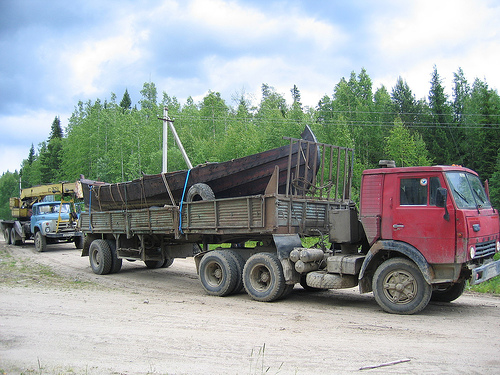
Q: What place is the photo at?
A: It is at the road.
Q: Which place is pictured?
A: It is a road.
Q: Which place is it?
A: It is a road.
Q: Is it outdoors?
A: Yes, it is outdoors.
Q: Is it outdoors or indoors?
A: It is outdoors.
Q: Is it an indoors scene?
A: No, it is outdoors.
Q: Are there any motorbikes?
A: No, there are no motorbikes.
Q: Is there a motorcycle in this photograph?
A: No, there are no motorcycles.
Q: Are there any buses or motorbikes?
A: No, there are no motorbikes or buses.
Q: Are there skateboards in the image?
A: No, there are no skateboards.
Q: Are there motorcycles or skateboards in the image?
A: No, there are no skateboards or motorcycles.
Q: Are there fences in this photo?
A: No, there are no fences.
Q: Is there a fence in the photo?
A: No, there are no fences.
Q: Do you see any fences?
A: No, there are no fences.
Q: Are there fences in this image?
A: No, there are no fences.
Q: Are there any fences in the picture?
A: No, there are no fences.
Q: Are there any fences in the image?
A: No, there are no fences.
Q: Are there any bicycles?
A: No, there are no bicycles.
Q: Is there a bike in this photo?
A: No, there are no bikes.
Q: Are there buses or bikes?
A: No, there are no bikes or buses.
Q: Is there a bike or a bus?
A: No, there are no bikes or buses.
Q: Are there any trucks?
A: Yes, there is a truck.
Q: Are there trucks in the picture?
A: Yes, there is a truck.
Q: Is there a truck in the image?
A: Yes, there is a truck.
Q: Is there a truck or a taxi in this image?
A: Yes, there is a truck.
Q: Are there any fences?
A: No, there are no fences.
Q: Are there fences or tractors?
A: No, there are no fences or tractors.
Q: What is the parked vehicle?
A: The vehicle is a truck.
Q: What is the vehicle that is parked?
A: The vehicle is a truck.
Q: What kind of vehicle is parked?
A: The vehicle is a truck.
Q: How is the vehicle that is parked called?
A: The vehicle is a truck.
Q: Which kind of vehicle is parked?
A: The vehicle is a truck.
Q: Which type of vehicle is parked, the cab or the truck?
A: The truck is parked.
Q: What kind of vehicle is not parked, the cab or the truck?
A: The cab is not parked.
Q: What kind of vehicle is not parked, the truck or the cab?
A: The cab is not parked.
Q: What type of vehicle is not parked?
A: The vehicle is a taxi.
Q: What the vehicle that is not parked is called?
A: The vehicle is a taxi.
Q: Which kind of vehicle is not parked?
A: The vehicle is a taxi.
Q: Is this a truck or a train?
A: This is a truck.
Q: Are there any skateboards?
A: No, there are no skateboards.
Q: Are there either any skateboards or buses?
A: No, there are no skateboards or buses.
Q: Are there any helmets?
A: No, there are no helmets.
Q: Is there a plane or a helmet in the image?
A: No, there are no helmets or airplanes.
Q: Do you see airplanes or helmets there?
A: No, there are no helmets or airplanes.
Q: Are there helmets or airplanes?
A: No, there are no helmets or airplanes.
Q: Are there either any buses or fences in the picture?
A: No, there are no fences or buses.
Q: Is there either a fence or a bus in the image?
A: No, there are no fences or buses.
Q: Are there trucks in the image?
A: Yes, there is a truck.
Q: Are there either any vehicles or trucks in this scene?
A: Yes, there is a truck.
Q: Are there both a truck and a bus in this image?
A: No, there is a truck but no buses.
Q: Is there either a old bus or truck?
A: Yes, there is an old truck.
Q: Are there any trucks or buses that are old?
A: Yes, the truck is old.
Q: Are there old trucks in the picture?
A: Yes, there is an old truck.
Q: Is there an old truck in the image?
A: Yes, there is an old truck.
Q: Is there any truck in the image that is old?
A: Yes, there is a truck that is old.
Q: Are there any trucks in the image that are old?
A: Yes, there is a truck that is old.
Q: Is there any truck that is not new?
A: Yes, there is a old truck.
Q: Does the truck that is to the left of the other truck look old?
A: Yes, the truck is old.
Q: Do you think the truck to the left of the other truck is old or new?
A: The truck is old.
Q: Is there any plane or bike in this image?
A: No, there are no bikes or airplanes.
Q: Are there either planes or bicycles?
A: No, there are no bicycles or planes.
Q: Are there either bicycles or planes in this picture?
A: No, there are no bicycles or planes.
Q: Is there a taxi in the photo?
A: Yes, there is a taxi.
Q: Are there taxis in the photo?
A: Yes, there is a taxi.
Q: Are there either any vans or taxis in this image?
A: Yes, there is a taxi.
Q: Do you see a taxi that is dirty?
A: Yes, there is a dirty taxi.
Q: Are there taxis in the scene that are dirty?
A: Yes, there is a taxi that is dirty.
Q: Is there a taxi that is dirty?
A: Yes, there is a taxi that is dirty.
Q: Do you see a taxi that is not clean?
A: Yes, there is a dirty taxi.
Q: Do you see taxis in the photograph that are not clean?
A: Yes, there is a dirty taxi.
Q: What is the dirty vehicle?
A: The vehicle is a taxi.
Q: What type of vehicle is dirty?
A: The vehicle is a taxi.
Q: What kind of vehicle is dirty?
A: The vehicle is a taxi.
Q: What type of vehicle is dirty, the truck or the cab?
A: The cab is dirty.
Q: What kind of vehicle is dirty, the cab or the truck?
A: The cab is dirty.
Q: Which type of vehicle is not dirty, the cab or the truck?
A: The truck is not dirty.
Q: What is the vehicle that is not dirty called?
A: The vehicle is a truck.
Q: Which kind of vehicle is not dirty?
A: The vehicle is a truck.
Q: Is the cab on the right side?
A: Yes, the cab is on the right of the image.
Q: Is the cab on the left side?
A: No, the cab is on the right of the image.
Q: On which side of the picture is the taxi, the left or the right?
A: The taxi is on the right of the image.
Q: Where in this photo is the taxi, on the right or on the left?
A: The taxi is on the right of the image.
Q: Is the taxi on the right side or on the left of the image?
A: The taxi is on the right of the image.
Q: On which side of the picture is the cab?
A: The cab is on the right of the image.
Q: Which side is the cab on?
A: The cab is on the right of the image.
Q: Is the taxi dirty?
A: Yes, the taxi is dirty.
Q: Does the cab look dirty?
A: Yes, the cab is dirty.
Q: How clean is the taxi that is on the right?
A: The cab is dirty.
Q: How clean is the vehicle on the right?
A: The cab is dirty.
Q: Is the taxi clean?
A: No, the taxi is dirty.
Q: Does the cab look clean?
A: No, the cab is dirty.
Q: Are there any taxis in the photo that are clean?
A: No, there is a taxi but it is dirty.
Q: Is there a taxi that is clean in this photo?
A: No, there is a taxi but it is dirty.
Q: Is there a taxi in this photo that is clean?
A: No, there is a taxi but it is dirty.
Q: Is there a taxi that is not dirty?
A: No, there is a taxi but it is dirty.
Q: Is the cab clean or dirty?
A: The cab is dirty.